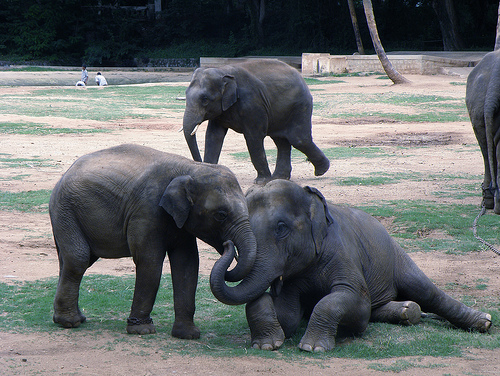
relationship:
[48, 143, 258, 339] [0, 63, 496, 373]
elephant in field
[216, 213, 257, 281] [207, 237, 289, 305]
trunk touching trunk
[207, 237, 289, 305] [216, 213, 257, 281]
trunk touching trunk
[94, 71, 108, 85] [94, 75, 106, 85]
people wears shirt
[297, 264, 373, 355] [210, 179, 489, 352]
leg of elephant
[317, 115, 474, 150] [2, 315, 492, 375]
patch of dirt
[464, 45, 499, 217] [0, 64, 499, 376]
elephants on field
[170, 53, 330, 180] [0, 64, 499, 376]
elephants on field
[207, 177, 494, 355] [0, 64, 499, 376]
elephants on field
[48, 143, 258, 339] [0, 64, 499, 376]
elephant on field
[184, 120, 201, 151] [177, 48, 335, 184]
tusk on elephant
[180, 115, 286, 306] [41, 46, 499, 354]
trunks on elephants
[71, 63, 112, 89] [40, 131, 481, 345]
people standing behind elephants